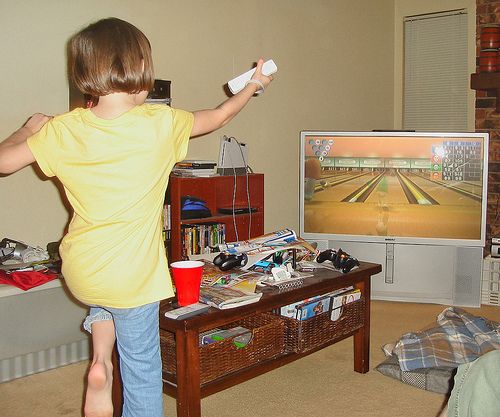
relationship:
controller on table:
[315, 247, 360, 272] [112, 259, 381, 414]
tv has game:
[300, 130, 487, 248] [323, 147, 468, 227]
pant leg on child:
[112, 309, 165, 414] [0, 17, 275, 417]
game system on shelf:
[214, 134, 249, 174] [170, 169, 265, 178]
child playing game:
[0, 17, 275, 417] [303, 136, 484, 240]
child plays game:
[0, 17, 275, 417] [303, 136, 484, 240]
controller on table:
[316, 248, 360, 274] [90, 246, 384, 413]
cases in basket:
[271, 284, 361, 320] [266, 297, 365, 355]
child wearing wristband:
[0, 17, 275, 417] [248, 75, 268, 94]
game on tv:
[305, 133, 480, 240] [289, 122, 494, 311]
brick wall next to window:
[469, 0, 499, 245] [394, 7, 481, 142]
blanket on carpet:
[382, 303, 499, 389] [0, 301, 500, 415]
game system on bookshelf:
[217, 135, 249, 176] [171, 173, 265, 262]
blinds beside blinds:
[406, 20, 466, 125] [402, 14, 468, 133]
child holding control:
[0, 17, 275, 417] [227, 59, 278, 95]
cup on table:
[166, 252, 208, 304] [158, 242, 383, 413]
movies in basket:
[296, 299, 361, 312] [276, 295, 367, 352]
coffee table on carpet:
[143, 243, 385, 414] [253, 359, 455, 414]